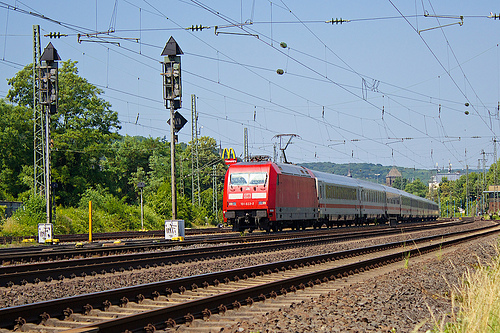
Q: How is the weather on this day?
A: It is clear.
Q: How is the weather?
A: It is clear.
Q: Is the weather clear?
A: Yes, it is clear.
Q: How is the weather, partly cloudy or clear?
A: It is clear.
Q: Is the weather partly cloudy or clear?
A: It is clear.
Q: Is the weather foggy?
A: No, it is clear.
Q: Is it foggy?
A: No, it is clear.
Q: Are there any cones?
A: No, there are no cones.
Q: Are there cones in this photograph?
A: No, there are no cones.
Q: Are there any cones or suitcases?
A: No, there are no cones or suitcases.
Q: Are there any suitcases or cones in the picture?
A: No, there are no cones or suitcases.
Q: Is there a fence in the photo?
A: No, there are no fences.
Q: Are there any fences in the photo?
A: No, there are no fences.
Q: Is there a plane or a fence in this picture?
A: No, there are no fences or airplanes.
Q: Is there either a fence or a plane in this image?
A: No, there are no fences or airplanes.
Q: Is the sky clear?
A: Yes, the sky is clear.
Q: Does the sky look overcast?
A: No, the sky is clear.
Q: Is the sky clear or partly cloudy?
A: The sky is clear.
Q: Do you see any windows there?
A: Yes, there are windows.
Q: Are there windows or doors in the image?
A: Yes, there are windows.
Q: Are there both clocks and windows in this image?
A: No, there are windows but no clocks.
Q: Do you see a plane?
A: No, there are no airplanes.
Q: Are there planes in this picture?
A: No, there are no planes.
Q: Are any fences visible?
A: No, there are no fences.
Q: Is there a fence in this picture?
A: No, there are no fences.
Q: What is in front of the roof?
A: The trees are in front of the roof.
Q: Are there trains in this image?
A: Yes, there is a train.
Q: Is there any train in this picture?
A: Yes, there is a train.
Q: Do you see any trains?
A: Yes, there is a train.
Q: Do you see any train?
A: Yes, there is a train.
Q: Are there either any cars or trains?
A: Yes, there is a train.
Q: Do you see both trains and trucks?
A: No, there is a train but no trucks.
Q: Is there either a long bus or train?
A: Yes, there is a long train.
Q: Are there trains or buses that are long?
A: Yes, the train is long.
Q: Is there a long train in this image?
A: Yes, there is a long train.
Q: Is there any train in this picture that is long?
A: Yes, there is a train that is long.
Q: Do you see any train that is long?
A: Yes, there is a train that is long.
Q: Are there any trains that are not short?
A: Yes, there is a long train.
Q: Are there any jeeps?
A: No, there are no jeeps.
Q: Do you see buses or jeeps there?
A: No, there are no jeeps or buses.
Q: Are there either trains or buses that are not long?
A: No, there is a train but it is long.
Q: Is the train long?
A: Yes, the train is long.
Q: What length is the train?
A: The train is long.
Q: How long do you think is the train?
A: The train is long.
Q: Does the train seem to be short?
A: No, the train is long.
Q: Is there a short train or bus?
A: No, there is a train but it is long.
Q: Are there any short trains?
A: No, there is a train but it is long.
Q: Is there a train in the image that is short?
A: No, there is a train but it is long.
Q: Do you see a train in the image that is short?
A: No, there is a train but it is long.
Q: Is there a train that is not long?
A: No, there is a train but it is long.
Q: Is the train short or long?
A: The train is long.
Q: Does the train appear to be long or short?
A: The train is long.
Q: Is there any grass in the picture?
A: Yes, there is grass.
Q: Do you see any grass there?
A: Yes, there is grass.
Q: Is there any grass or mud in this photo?
A: Yes, there is grass.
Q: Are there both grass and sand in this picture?
A: No, there is grass but no sand.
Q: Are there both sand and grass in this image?
A: No, there is grass but no sand.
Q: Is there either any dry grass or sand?
A: Yes, there is dry grass.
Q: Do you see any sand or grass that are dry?
A: Yes, the grass is dry.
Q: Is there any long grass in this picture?
A: Yes, there is long grass.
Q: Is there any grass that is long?
A: Yes, there is grass that is long.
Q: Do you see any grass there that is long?
A: Yes, there is grass that is long.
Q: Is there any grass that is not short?
A: Yes, there is long grass.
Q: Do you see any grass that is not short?
A: Yes, there is long grass.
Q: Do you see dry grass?
A: Yes, there is dry grass.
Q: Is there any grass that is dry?
A: Yes, there is grass that is dry.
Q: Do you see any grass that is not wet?
A: Yes, there is dry grass.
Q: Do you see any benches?
A: No, there are no benches.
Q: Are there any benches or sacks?
A: No, there are no benches or sacks.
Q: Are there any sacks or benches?
A: No, there are no benches or sacks.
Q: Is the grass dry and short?
A: No, the grass is dry but long.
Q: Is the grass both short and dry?
A: No, the grass is dry but long.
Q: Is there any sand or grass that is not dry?
A: No, there is grass but it is dry.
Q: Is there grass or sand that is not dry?
A: No, there is grass but it is dry.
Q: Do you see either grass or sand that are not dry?
A: No, there is grass but it is dry.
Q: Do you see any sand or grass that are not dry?
A: No, there is grass but it is dry.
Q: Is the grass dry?
A: Yes, the grass is dry.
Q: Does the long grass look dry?
A: Yes, the grass is dry.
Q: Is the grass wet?
A: No, the grass is dry.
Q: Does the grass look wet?
A: No, the grass is dry.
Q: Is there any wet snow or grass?
A: No, there is grass but it is dry.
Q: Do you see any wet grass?
A: No, there is grass but it is dry.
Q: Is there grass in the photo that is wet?
A: No, there is grass but it is dry.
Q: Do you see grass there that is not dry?
A: No, there is grass but it is dry.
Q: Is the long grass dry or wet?
A: The grass is dry.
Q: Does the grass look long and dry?
A: Yes, the grass is long and dry.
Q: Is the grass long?
A: Yes, the grass is long.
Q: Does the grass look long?
A: Yes, the grass is long.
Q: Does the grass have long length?
A: Yes, the grass is long.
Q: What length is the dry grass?
A: The grass is long.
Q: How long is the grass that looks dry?
A: The grass is long.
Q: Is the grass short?
A: No, the grass is long.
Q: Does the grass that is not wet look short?
A: No, the grass is long.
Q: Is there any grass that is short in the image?
A: No, there is grass but it is long.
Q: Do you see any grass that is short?
A: No, there is grass but it is long.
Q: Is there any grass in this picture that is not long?
A: No, there is grass but it is long.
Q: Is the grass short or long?
A: The grass is long.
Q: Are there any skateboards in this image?
A: No, there are no skateboards.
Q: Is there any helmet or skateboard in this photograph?
A: No, there are no skateboards or helmets.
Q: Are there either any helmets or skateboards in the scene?
A: No, there are no skateboards or helmets.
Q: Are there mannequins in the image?
A: No, there are no mannequins.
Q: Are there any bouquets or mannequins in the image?
A: No, there are no mannequins or bouquets.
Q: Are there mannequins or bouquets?
A: No, there are no mannequins or bouquets.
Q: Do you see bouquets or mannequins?
A: No, there are no mannequins or bouquets.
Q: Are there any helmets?
A: No, there are no helmets.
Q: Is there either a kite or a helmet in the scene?
A: No, there are no helmets or kites.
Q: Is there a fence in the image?
A: No, there are no fences.